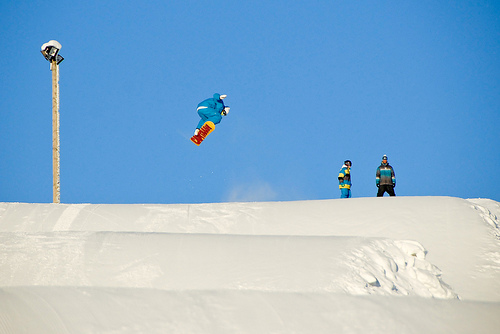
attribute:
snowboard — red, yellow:
[192, 121, 217, 149]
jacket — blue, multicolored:
[196, 91, 225, 120]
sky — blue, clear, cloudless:
[104, 58, 137, 75]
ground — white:
[113, 224, 159, 252]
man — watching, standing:
[340, 156, 353, 193]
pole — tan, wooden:
[45, 63, 58, 213]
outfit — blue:
[205, 93, 233, 118]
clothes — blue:
[377, 164, 397, 187]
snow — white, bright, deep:
[61, 239, 91, 278]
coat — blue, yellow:
[339, 165, 352, 184]